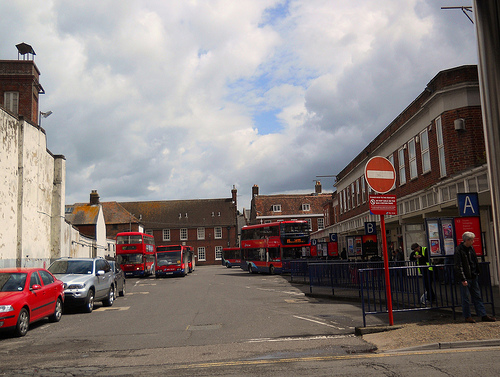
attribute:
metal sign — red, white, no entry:
[355, 154, 406, 199]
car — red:
[0, 267, 67, 335]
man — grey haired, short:
[455, 228, 487, 321]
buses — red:
[119, 203, 389, 271]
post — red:
[379, 211, 394, 324]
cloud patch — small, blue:
[247, 0, 312, 41]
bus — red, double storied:
[238, 219, 312, 274]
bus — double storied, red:
[112, 230, 154, 275]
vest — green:
[410, 244, 432, 267]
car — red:
[4, 246, 61, 367]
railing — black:
[355, 258, 495, 326]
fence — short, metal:
[284, 252, 494, 319]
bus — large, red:
[112, 225, 160, 281]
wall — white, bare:
[67, 202, 350, 272]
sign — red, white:
[366, 156, 397, 193]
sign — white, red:
[369, 192, 397, 211]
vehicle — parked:
[108, 224, 193, 301]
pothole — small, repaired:
[183, 318, 227, 332]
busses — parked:
[108, 225, 335, 275]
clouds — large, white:
[58, 6, 205, 142]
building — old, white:
[0, 120, 75, 270]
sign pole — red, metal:
[358, 153, 404, 328]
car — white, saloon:
[42, 256, 117, 308]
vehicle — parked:
[46, 255, 116, 309]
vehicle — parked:
[99, 256, 124, 291]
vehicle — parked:
[109, 232, 156, 277]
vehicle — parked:
[154, 244, 195, 273]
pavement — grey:
[1, 261, 498, 375]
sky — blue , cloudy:
[2, 3, 479, 212]